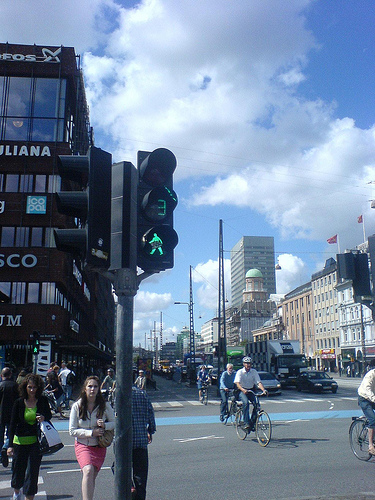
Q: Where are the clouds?
A: In the sky.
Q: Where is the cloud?
A: In the sky.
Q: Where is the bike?
A: In the street.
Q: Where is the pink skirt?
A: On the woman.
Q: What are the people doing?
A: Commuting.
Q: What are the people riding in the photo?
A: Bikes.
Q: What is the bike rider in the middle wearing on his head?
A: A helmet.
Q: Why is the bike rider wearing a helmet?
A: For safety purposes.